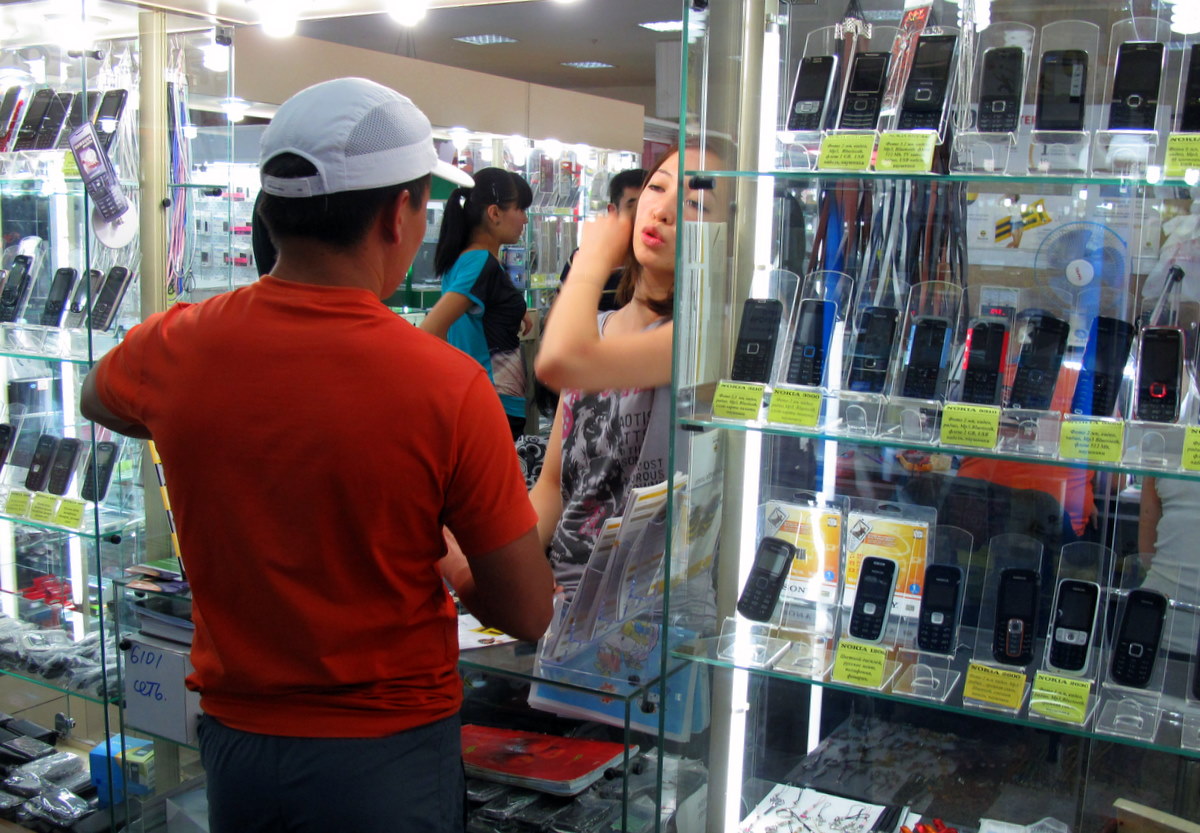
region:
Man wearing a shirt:
[96, 260, 558, 738]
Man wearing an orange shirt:
[89, 262, 557, 742]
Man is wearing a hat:
[245, 73, 490, 220]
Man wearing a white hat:
[238, 63, 496, 215]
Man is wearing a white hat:
[240, 68, 495, 213]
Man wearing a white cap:
[245, 68, 488, 213]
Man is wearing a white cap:
[248, 68, 486, 208]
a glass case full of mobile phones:
[676, 0, 1197, 831]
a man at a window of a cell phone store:
[83, 76, 559, 828]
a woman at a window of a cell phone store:
[525, 143, 710, 595]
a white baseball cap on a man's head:
[256, 81, 472, 201]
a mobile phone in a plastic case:
[731, 292, 777, 381]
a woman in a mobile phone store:
[410, 164, 545, 414]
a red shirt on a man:
[102, 275, 542, 743]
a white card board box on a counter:
[112, 637, 199, 746]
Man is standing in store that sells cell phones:
[84, 81, 579, 828]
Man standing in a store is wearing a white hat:
[98, 55, 555, 821]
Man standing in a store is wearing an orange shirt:
[54, 69, 547, 830]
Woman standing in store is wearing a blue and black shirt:
[434, 149, 542, 430]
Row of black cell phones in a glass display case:
[744, 544, 1172, 696]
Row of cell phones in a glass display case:
[732, 298, 1194, 421]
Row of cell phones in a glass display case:
[774, 36, 1199, 137]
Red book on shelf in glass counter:
[470, 703, 634, 805]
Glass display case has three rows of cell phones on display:
[691, 4, 1198, 828]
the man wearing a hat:
[84, 70, 555, 827]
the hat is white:
[255, 74, 477, 204]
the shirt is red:
[89, 271, 538, 737]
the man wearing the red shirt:
[80, 72, 556, 829]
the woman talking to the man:
[84, 74, 735, 828]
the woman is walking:
[421, 158, 534, 458]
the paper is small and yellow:
[709, 381, 758, 422]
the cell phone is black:
[732, 295, 783, 384]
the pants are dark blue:
[198, 705, 475, 830]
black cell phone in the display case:
[1047, 579, 1098, 668]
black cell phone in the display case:
[990, 565, 1034, 664]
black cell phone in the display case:
[912, 555, 960, 647]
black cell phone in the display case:
[732, 536, 792, 620]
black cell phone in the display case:
[781, 296, 834, 392]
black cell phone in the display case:
[841, 295, 899, 404]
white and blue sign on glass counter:
[120, 635, 188, 743]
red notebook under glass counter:
[457, 723, 637, 796]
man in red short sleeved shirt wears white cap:
[80, 75, 554, 831]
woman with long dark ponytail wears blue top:
[425, 167, 534, 446]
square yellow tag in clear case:
[876, 129, 929, 171]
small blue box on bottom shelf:
[89, 726, 154, 804]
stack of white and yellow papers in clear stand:
[545, 469, 690, 669]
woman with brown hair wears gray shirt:
[517, 143, 734, 611]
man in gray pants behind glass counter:
[82, 78, 556, 825]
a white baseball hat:
[218, 70, 487, 232]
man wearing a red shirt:
[96, 256, 550, 712]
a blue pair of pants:
[166, 681, 491, 830]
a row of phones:
[708, 480, 1174, 714]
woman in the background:
[427, 129, 564, 399]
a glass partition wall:
[612, 12, 732, 829]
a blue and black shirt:
[427, 228, 541, 361]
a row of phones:
[705, 461, 1198, 718]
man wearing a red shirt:
[63, 245, 635, 745]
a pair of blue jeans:
[171, 679, 493, 829]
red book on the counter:
[454, 677, 664, 815]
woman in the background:
[425, 151, 567, 375]